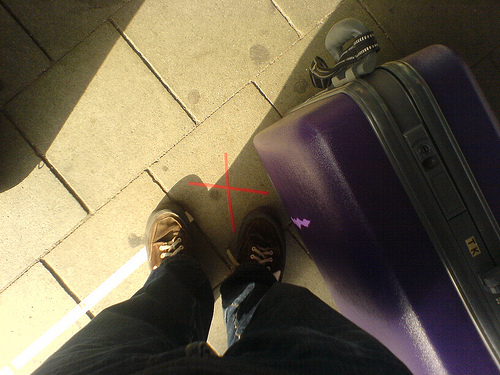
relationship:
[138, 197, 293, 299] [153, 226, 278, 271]
shoes with laces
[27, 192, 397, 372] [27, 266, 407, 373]
person wearing pants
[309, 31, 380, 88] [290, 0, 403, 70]
strap on handle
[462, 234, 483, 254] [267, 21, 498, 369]
sticker on suitcase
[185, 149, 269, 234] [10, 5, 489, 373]
x on floor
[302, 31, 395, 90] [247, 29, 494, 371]
strap on suitcase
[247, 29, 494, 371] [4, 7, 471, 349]
suitcase on ground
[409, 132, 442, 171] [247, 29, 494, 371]
lock on suitcase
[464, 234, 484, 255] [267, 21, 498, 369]
initials on suitcase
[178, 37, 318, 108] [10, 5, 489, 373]
spots on floor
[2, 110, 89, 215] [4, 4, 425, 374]
grout between tiles